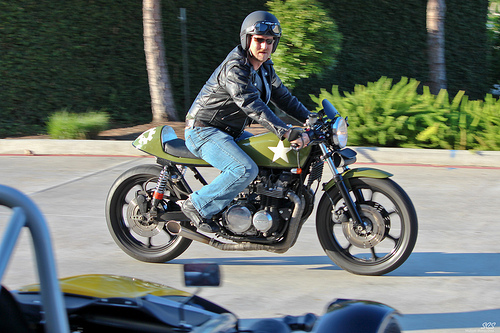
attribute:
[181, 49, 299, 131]
jacket — man's , leather 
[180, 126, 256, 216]
jeans — blue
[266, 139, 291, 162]
star — white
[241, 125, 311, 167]
tank — gas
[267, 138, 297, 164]
star — white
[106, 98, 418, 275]
motorcycle — green, white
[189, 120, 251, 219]
jeans — blue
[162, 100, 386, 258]
motorcycle — green 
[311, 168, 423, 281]
wheel — is front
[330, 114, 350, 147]
headlight — white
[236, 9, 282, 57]
helmet — black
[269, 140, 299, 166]
white star — white 